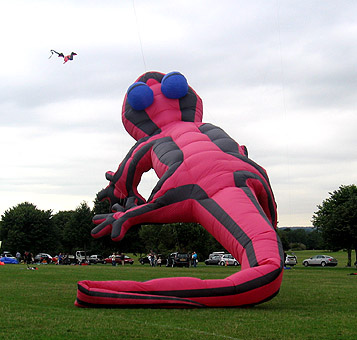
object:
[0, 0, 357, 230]
sky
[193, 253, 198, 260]
shirt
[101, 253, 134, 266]
car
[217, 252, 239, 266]
car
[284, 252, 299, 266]
car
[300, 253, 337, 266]
car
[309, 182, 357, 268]
tree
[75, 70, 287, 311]
lizard balloon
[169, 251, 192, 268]
vehicle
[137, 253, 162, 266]
vehicle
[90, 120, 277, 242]
body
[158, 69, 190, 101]
blue eyes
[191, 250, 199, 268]
people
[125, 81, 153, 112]
eye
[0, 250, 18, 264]
cars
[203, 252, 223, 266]
vehicle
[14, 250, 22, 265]
person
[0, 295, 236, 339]
cable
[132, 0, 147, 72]
wire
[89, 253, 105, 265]
cars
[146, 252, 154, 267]
person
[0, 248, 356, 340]
grass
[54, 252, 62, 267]
people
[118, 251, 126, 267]
people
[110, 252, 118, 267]
people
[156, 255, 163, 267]
people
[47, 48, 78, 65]
kite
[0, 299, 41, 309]
white line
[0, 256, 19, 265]
tarp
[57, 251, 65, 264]
people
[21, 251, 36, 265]
object